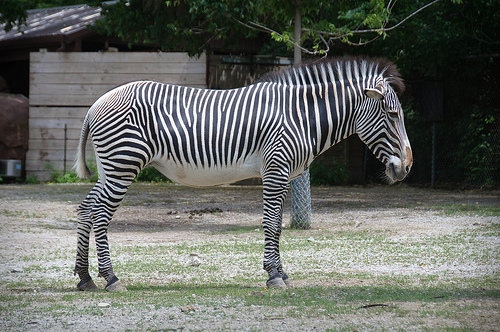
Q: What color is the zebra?
A: Black and white.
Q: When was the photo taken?
A: During the day.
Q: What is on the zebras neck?
A: Fur.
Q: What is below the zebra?
A: The ground.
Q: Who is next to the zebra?
A: No one.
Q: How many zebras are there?
A: One.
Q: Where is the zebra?
A: The zoo.